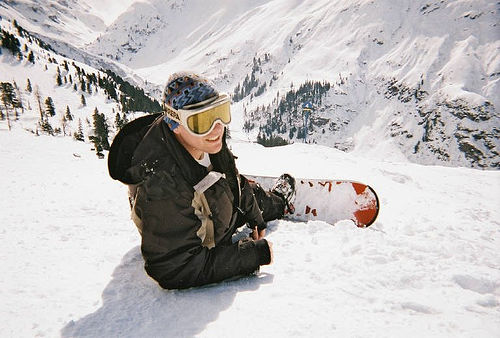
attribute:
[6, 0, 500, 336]
mountain. — covered.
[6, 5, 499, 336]
snow. — white.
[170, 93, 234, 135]
goggles — white., gold., yellow.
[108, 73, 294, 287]
man — sitting., smiling., laying.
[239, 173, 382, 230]
snowboard — white., red., covered., orange.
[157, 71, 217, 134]
hat — purple., blue.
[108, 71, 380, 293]
snowboarder — resting., caucasian., smiling.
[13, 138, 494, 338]
ground — covered.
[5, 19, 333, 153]
trees — pine., scattered., green., covered., far.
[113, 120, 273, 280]
jacket — brown., black.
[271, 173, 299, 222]
boot — clipped., strapped.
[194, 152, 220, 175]
shirt — white.